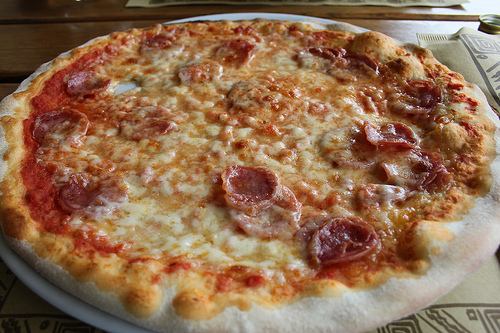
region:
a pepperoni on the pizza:
[202, 147, 286, 242]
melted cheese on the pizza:
[114, 167, 237, 262]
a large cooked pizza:
[6, 10, 498, 321]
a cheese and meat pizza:
[7, 19, 498, 328]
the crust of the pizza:
[422, 166, 494, 321]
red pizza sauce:
[47, 213, 139, 278]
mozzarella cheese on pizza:
[187, 81, 323, 161]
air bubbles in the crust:
[332, 18, 414, 103]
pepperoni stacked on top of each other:
[291, 189, 408, 299]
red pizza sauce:
[11, 147, 88, 252]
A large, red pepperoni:
[221, 162, 280, 208]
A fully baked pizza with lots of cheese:
[1, 8, 498, 328]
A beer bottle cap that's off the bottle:
[478, 13, 498, 38]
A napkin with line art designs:
[417, 30, 499, 105]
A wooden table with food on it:
[0, 0, 499, 102]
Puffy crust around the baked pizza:
[38, 280, 481, 331]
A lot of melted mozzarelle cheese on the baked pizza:
[44, 41, 474, 278]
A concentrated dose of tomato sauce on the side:
[21, 42, 84, 243]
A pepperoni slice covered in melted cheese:
[225, 76, 290, 116]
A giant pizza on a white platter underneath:
[2, 13, 499, 331]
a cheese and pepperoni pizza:
[17, 7, 489, 317]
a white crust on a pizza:
[277, 300, 352, 330]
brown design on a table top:
[435, 301, 494, 331]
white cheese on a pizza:
[140, 212, 235, 264]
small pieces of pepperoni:
[312, 217, 379, 264]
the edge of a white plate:
[14, 259, 116, 326]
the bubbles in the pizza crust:
[366, 30, 432, 87]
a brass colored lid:
[472, 11, 497, 28]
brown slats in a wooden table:
[5, 11, 80, 57]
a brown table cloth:
[419, 25, 482, 69]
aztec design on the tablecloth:
[410, 303, 492, 329]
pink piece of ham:
[227, 160, 302, 231]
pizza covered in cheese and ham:
[35, 35, 486, 302]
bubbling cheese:
[135, 155, 220, 255]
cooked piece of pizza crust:
[337, 185, 497, 280]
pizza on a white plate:
[10, 25, 472, 317]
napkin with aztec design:
[415, 30, 495, 110]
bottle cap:
[482, 12, 499, 34]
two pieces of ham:
[215, 165, 297, 237]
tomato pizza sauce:
[27, 82, 70, 237]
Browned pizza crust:
[328, 15, 493, 300]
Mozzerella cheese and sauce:
[81, 135, 300, 327]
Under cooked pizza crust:
[113, 264, 483, 331]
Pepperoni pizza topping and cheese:
[208, 158, 400, 283]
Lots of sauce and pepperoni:
[19, 30, 158, 291]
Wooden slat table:
[6, 7, 498, 100]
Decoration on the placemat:
[386, 11, 496, 330]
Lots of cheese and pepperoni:
[46, 20, 445, 289]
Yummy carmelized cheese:
[306, 26, 498, 166]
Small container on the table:
[463, 9, 499, 47]